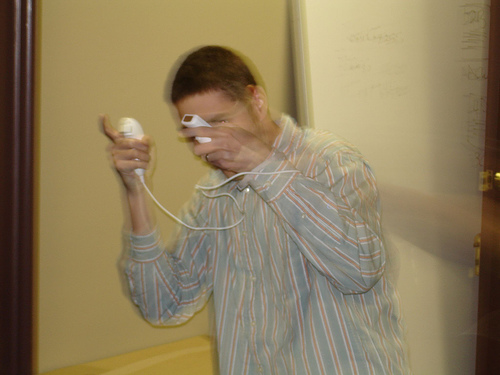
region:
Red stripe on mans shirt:
[212, 314, 223, 349]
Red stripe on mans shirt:
[309, 335, 328, 374]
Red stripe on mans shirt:
[324, 329, 341, 374]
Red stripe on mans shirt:
[337, 332, 357, 372]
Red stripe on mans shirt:
[353, 329, 373, 373]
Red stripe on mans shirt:
[364, 327, 396, 374]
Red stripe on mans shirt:
[388, 327, 413, 373]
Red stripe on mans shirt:
[287, 330, 302, 371]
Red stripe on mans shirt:
[273, 342, 293, 374]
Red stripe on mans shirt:
[257, 335, 280, 372]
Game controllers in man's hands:
[114, 113, 222, 167]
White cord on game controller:
[137, 168, 254, 230]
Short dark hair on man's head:
[167, 49, 253, 93]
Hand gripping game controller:
[97, 115, 149, 192]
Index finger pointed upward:
[98, 116, 115, 140]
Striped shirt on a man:
[125, 112, 408, 374]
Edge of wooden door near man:
[483, 7, 498, 374]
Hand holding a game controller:
[184, 120, 266, 171]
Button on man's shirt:
[240, 185, 250, 195]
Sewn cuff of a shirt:
[249, 149, 291, 197]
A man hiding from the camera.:
[171, 45, 410, 372]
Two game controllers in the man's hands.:
[86, 114, 267, 174]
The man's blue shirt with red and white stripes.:
[215, 308, 408, 371]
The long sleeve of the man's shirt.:
[241, 168, 398, 293]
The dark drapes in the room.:
[4, 0, 53, 373]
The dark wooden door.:
[474, 34, 498, 373]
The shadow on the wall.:
[403, 187, 473, 272]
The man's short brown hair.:
[161, 47, 243, 102]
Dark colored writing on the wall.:
[349, 12, 486, 133]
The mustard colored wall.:
[51, 28, 96, 246]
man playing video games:
[135, 56, 327, 373]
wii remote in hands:
[117, 120, 239, 209]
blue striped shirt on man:
[173, 169, 358, 359]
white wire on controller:
[156, 176, 258, 240]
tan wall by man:
[33, 6, 263, 323]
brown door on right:
[463, 16, 497, 319]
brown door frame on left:
[5, 26, 43, 371]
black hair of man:
[170, 45, 245, 87]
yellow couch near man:
[117, 334, 212, 374]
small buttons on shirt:
[251, 264, 260, 284]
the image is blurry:
[37, 2, 475, 352]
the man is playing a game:
[83, 29, 423, 356]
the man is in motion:
[59, 17, 416, 347]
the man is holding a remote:
[64, 50, 329, 282]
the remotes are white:
[66, 87, 309, 276]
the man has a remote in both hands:
[87, 40, 328, 280]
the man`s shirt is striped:
[57, 45, 399, 350]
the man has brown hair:
[136, 24, 275, 139]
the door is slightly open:
[410, 69, 499, 339]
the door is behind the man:
[97, 28, 496, 343]